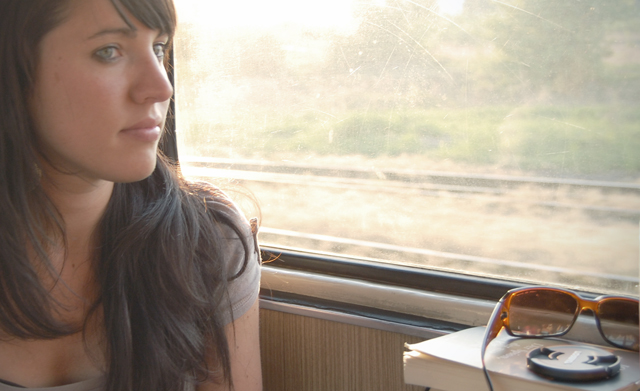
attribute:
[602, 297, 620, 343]
lens — dark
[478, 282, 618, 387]
sunglasses — amber , framed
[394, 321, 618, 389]
book — large, white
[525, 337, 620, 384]
disc — round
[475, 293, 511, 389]
arm — amber colored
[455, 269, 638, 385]
sunglasses — brown, a pair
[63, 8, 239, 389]
hair — long, dark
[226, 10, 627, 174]
trees — green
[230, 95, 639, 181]
bushes — green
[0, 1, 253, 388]
lady — young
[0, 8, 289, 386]
lady — young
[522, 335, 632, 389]
coffee mug-lid — spill proof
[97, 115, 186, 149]
lips — closed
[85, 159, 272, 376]
hair — dark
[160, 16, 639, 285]
window — suynny, scratched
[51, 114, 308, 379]
hair — black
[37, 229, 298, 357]
shirt — gray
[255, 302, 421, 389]
wall — brown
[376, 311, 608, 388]
book — white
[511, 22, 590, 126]
leaves — green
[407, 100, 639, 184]
grass — green